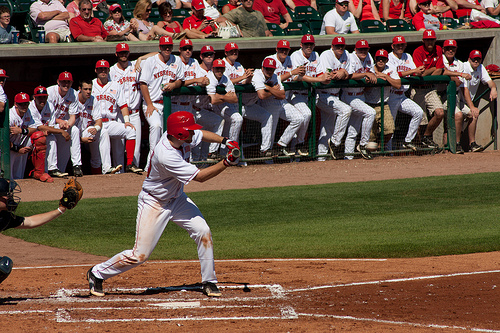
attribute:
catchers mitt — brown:
[58, 175, 94, 207]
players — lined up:
[13, 32, 489, 128]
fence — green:
[163, 76, 460, 150]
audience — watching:
[1, 2, 499, 43]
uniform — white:
[90, 129, 219, 293]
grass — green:
[215, 182, 499, 256]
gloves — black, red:
[220, 136, 242, 167]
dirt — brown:
[19, 258, 500, 332]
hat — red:
[299, 32, 321, 45]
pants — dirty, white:
[102, 190, 220, 283]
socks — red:
[123, 135, 136, 168]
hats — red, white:
[157, 34, 485, 69]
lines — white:
[57, 274, 495, 332]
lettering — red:
[95, 94, 118, 103]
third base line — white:
[299, 261, 499, 294]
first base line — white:
[309, 309, 499, 332]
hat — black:
[1, 179, 8, 191]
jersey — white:
[138, 133, 205, 199]